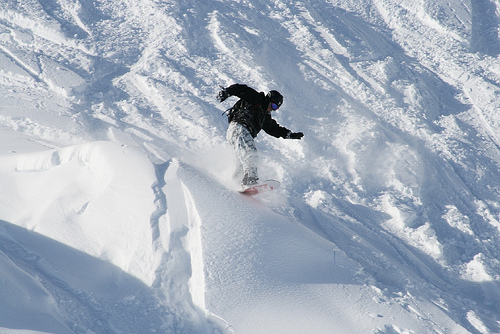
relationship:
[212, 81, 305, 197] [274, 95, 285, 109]
person wearing goggles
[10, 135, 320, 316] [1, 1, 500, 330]
mound of snow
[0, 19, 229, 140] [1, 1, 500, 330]
tracks in snow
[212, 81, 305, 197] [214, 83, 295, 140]
person wearing jacket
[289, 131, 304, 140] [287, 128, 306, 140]
glove on left hand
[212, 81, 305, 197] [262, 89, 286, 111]
person wearing hat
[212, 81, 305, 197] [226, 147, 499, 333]
person going downhill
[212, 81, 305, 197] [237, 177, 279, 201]
person on snowboard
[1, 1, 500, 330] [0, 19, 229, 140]
snow has tracks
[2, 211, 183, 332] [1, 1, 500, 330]
shadow on snow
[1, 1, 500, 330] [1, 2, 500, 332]
snow covering mountain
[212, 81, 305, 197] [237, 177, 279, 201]
person riding snowboard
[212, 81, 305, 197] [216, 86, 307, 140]
person wearing gloves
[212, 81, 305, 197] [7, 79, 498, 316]
person on slope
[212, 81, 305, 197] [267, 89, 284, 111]
person wearing hat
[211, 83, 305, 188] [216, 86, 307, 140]
boy wearing gloves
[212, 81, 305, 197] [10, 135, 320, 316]
person on mound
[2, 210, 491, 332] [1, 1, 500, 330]
shadows on snow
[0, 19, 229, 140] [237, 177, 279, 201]
tracks from snowboard